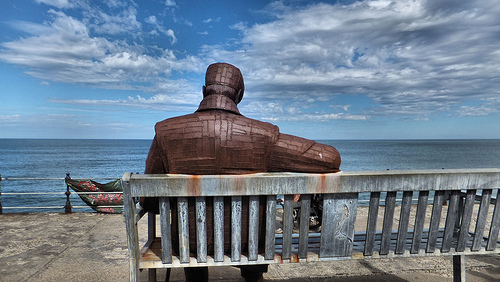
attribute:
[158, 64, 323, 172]
statue — wooden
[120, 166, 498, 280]
bench — metal, gray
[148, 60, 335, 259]
wooden figure — brown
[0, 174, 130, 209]
fence — silver, metal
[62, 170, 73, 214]
post — black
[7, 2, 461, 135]
sky — blue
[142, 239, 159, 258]
patch — brown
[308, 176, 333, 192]
rust patch — brown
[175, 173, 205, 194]
rust patch — brown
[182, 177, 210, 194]
rust patch — brown